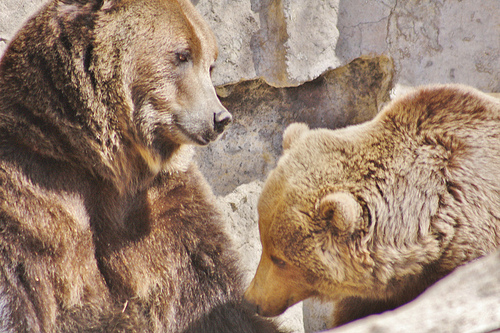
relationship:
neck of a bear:
[346, 126, 446, 286] [238, 64, 498, 304]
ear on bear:
[307, 188, 364, 241] [239, 76, 499, 320]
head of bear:
[249, 120, 389, 311] [239, 76, 499, 320]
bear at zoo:
[2, 0, 294, 331] [223, 60, 367, 137]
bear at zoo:
[239, 76, 499, 320] [223, 60, 367, 137]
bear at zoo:
[2, 0, 294, 331] [240, 53, 336, 96]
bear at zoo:
[239, 76, 499, 320] [240, 53, 336, 96]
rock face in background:
[1, 1, 498, 331] [223, 61, 325, 113]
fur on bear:
[19, 10, 302, 327] [212, 118, 427, 230]